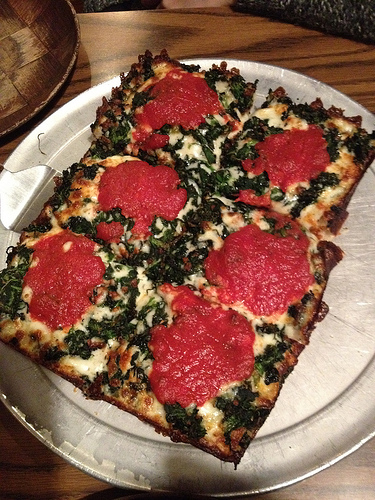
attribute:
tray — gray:
[249, 328, 374, 499]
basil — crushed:
[200, 170, 237, 190]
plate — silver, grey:
[2, 50, 373, 498]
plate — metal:
[8, 39, 372, 437]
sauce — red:
[19, 57, 329, 407]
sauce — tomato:
[146, 281, 255, 406]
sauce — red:
[204, 221, 314, 319]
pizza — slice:
[95, 95, 373, 327]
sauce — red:
[126, 286, 270, 414]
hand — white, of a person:
[161, 3, 232, 14]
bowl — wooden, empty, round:
[0, 4, 78, 129]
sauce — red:
[166, 293, 246, 393]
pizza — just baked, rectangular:
[15, 102, 359, 418]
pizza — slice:
[23, 60, 371, 453]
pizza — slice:
[93, 64, 281, 184]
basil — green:
[154, 226, 197, 275]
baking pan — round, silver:
[292, 375, 362, 490]